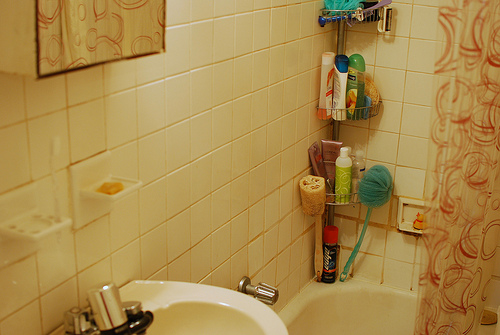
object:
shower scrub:
[338, 163, 393, 282]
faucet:
[60, 283, 156, 335]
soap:
[96, 182, 125, 195]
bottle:
[321, 225, 338, 283]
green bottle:
[343, 52, 366, 120]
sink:
[53, 278, 296, 334]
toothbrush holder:
[0, 206, 73, 242]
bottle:
[331, 54, 351, 120]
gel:
[321, 225, 340, 285]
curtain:
[411, 0, 500, 335]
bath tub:
[278, 269, 422, 335]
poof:
[339, 162, 394, 282]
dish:
[79, 173, 144, 201]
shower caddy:
[298, 0, 392, 287]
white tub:
[279, 275, 421, 334]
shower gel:
[345, 52, 366, 121]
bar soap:
[97, 181, 124, 195]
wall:
[5, 2, 346, 332]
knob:
[238, 274, 278, 306]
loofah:
[299, 175, 327, 281]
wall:
[325, 3, 477, 284]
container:
[298, 0, 398, 287]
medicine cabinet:
[33, 1, 166, 80]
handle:
[314, 216, 325, 280]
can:
[323, 226, 339, 284]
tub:
[275, 270, 424, 335]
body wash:
[345, 79, 365, 120]